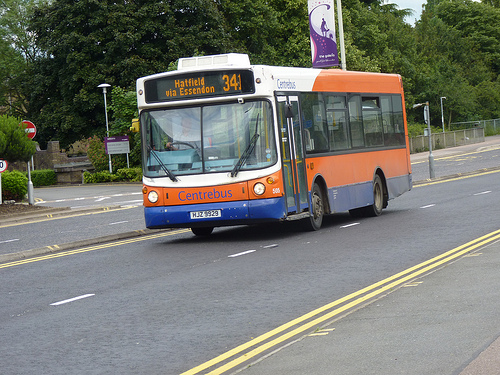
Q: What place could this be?
A: It is a road.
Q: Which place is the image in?
A: It is at the road.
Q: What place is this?
A: It is a road.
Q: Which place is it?
A: It is a road.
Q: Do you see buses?
A: Yes, there is a bus.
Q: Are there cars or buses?
A: Yes, there is a bus.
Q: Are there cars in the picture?
A: No, there are no cars.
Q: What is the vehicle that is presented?
A: The vehicle is a bus.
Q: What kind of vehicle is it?
A: The vehicle is a bus.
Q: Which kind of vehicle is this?
A: This is a bus.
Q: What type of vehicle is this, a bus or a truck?
A: This is a bus.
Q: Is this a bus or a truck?
A: This is a bus.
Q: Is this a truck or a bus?
A: This is a bus.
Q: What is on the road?
A: The bus is on the road.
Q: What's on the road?
A: The bus is on the road.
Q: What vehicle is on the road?
A: The vehicle is a bus.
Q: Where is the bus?
A: The bus is on the road.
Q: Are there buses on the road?
A: Yes, there is a bus on the road.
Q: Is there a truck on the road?
A: No, there is a bus on the road.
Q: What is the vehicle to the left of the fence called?
A: The vehicle is a bus.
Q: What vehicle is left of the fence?
A: The vehicle is a bus.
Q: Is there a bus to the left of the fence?
A: Yes, there is a bus to the left of the fence.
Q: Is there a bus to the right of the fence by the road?
A: No, the bus is to the left of the fence.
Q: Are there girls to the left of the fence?
A: No, there is a bus to the left of the fence.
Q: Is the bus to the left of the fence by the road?
A: Yes, the bus is to the left of the fence.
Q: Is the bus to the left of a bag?
A: No, the bus is to the left of the fence.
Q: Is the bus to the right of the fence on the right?
A: No, the bus is to the left of the fence.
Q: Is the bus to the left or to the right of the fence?
A: The bus is to the left of the fence.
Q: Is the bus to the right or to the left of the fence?
A: The bus is to the left of the fence.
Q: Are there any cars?
A: No, there are no cars.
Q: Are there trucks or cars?
A: No, there are no cars or trucks.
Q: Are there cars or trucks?
A: No, there are no cars or trucks.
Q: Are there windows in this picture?
A: Yes, there is a window.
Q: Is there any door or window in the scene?
A: Yes, there is a window.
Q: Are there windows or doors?
A: Yes, there is a window.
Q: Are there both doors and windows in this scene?
A: Yes, there are both a window and a door.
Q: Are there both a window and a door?
A: Yes, there are both a window and a door.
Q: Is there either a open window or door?
A: Yes, there is an open window.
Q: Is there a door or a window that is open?
A: Yes, the window is open.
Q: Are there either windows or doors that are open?
A: Yes, the window is open.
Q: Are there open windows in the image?
A: Yes, there is an open window.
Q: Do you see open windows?
A: Yes, there is an open window.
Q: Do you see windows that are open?
A: Yes, there is a window that is open.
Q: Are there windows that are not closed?
A: Yes, there is a open window.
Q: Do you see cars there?
A: No, there are no cars.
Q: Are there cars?
A: No, there are no cars.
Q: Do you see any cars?
A: No, there are no cars.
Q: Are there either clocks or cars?
A: No, there are no cars or clocks.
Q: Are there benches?
A: No, there are no benches.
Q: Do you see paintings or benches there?
A: No, there are no benches or paintings.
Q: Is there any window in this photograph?
A: Yes, there is a window.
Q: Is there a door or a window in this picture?
A: Yes, there is a window.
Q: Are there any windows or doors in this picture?
A: Yes, there is a window.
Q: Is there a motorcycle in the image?
A: No, there are no motorcycles.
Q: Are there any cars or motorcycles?
A: No, there are no motorcycles or cars.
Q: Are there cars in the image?
A: No, there are no cars.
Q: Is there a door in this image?
A: Yes, there are doors.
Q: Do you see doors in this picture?
A: Yes, there are doors.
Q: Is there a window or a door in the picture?
A: Yes, there are doors.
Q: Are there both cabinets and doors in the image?
A: No, there are doors but no cabinets.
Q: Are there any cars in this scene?
A: No, there are no cars.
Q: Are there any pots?
A: No, there are no pots.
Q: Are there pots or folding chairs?
A: No, there are no pots or folding chairs.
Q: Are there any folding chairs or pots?
A: No, there are no pots or folding chairs.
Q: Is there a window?
A: Yes, there is a window.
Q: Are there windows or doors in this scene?
A: Yes, there is a window.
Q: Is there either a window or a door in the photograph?
A: Yes, there is a window.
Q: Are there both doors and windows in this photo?
A: Yes, there are both a window and a door.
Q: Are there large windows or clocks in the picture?
A: Yes, there is a large window.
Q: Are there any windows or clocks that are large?
A: Yes, the window is large.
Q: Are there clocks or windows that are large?
A: Yes, the window is large.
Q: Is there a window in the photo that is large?
A: Yes, there is a large window.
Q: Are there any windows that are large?
A: Yes, there is a window that is large.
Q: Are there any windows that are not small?
A: Yes, there is a large window.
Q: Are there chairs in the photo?
A: No, there are no chairs.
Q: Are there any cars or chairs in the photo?
A: No, there are no chairs or cars.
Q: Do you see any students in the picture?
A: No, there are no students.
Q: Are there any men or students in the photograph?
A: No, there are no students or men.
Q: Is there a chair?
A: No, there are no chairs.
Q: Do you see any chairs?
A: No, there are no chairs.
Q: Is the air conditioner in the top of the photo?
A: Yes, the air conditioner is in the top of the image.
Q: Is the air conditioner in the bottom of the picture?
A: No, the air conditioner is in the top of the image.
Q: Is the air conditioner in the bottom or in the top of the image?
A: The air conditioner is in the top of the image.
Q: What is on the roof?
A: The air conditioner is on the roof.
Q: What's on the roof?
A: The air conditioner is on the roof.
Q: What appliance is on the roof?
A: The appliance is an air conditioner.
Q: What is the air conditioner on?
A: The air conditioner is on the roof.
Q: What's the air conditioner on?
A: The air conditioner is on the roof.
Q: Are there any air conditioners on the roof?
A: Yes, there is an air conditioner on the roof.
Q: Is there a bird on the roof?
A: No, there is an air conditioner on the roof.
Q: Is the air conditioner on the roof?
A: Yes, the air conditioner is on the roof.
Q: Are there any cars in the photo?
A: No, there are no cars.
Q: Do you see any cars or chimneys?
A: No, there are no cars or chimneys.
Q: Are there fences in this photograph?
A: Yes, there is a fence.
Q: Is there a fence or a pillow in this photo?
A: Yes, there is a fence.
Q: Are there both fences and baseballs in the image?
A: No, there is a fence but no baseballs.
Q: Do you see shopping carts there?
A: No, there are no shopping carts.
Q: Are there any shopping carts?
A: No, there are no shopping carts.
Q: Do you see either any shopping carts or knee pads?
A: No, there are no shopping carts or knee pads.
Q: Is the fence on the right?
A: Yes, the fence is on the right of the image.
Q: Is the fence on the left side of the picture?
A: No, the fence is on the right of the image.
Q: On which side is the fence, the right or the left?
A: The fence is on the right of the image.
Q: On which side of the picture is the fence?
A: The fence is on the right of the image.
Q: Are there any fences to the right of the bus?
A: Yes, there is a fence to the right of the bus.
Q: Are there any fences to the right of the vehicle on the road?
A: Yes, there is a fence to the right of the bus.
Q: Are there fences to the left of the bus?
A: No, the fence is to the right of the bus.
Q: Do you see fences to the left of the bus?
A: No, the fence is to the right of the bus.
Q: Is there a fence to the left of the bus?
A: No, the fence is to the right of the bus.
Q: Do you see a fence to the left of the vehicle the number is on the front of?
A: No, the fence is to the right of the bus.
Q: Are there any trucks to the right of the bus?
A: No, there is a fence to the right of the bus.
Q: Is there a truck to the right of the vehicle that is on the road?
A: No, there is a fence to the right of the bus.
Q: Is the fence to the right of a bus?
A: Yes, the fence is to the right of a bus.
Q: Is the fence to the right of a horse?
A: No, the fence is to the right of a bus.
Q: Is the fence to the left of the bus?
A: No, the fence is to the right of the bus.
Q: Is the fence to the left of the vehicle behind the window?
A: No, the fence is to the right of the bus.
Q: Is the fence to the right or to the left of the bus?
A: The fence is to the right of the bus.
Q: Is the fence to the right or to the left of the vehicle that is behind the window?
A: The fence is to the right of the bus.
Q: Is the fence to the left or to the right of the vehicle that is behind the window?
A: The fence is to the right of the bus.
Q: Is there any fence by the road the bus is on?
A: Yes, there is a fence by the road.